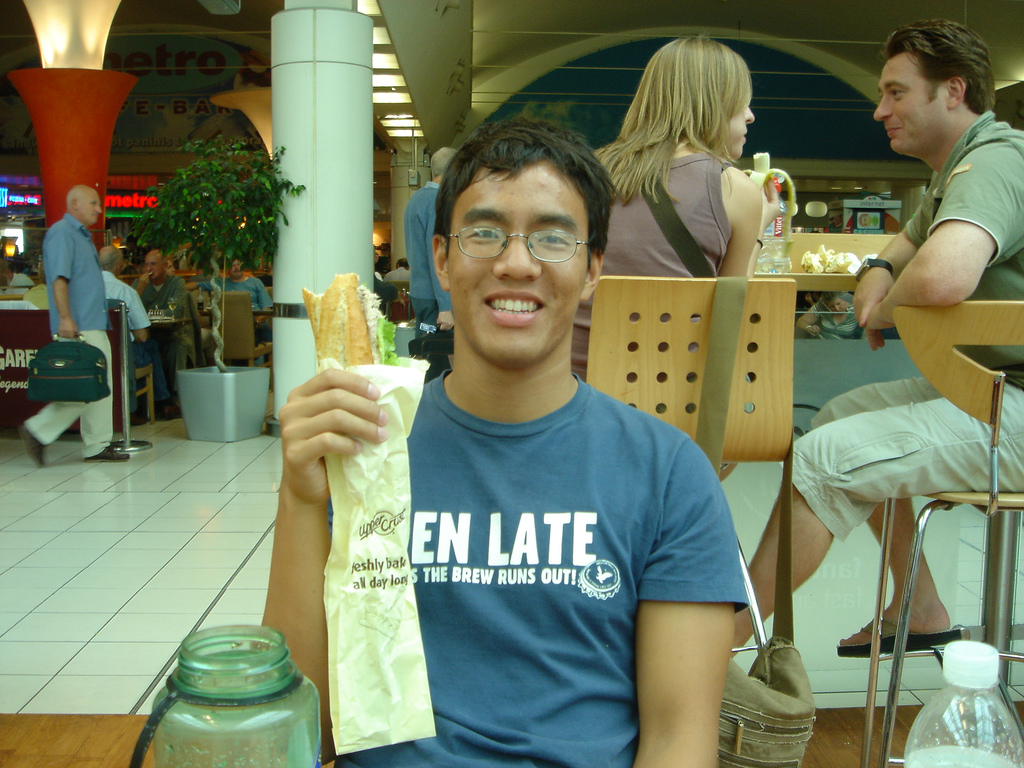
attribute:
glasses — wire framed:
[435, 226, 590, 261]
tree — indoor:
[150, 130, 297, 365]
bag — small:
[30, 338, 108, 406]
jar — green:
[147, 629, 326, 763]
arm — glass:
[256, 484, 324, 731]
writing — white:
[409, 513, 618, 596]